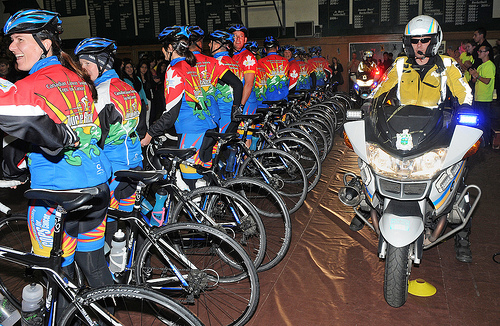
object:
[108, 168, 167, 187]
seat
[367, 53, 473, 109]
jacket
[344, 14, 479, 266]
man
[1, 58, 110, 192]
red/blue jacket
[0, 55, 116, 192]
blouse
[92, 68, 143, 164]
blouse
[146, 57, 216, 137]
blouse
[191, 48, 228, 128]
blouse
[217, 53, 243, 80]
blouse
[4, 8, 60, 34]
helmet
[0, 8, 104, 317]
cyclist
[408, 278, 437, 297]
oplate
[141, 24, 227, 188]
cyclist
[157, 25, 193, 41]
helmet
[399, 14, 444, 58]
helmet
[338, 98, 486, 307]
bike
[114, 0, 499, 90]
wall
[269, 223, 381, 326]
floor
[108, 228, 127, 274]
water bottle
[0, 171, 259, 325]
bicycle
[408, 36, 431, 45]
spectacle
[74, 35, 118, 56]
helmet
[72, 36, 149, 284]
cyclist